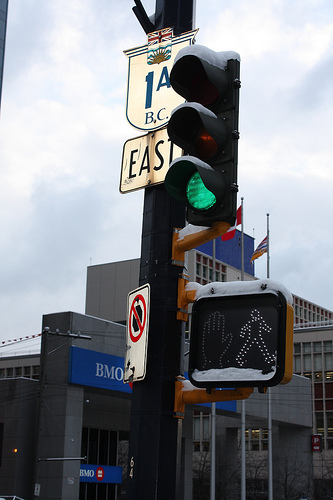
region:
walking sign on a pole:
[184, 269, 296, 409]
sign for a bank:
[77, 457, 126, 491]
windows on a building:
[309, 376, 331, 441]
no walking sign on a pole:
[121, 291, 156, 387]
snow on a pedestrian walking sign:
[200, 276, 282, 298]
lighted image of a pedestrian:
[232, 306, 279, 386]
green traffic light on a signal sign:
[159, 151, 229, 230]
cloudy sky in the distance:
[20, 10, 105, 210]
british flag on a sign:
[144, 25, 182, 50]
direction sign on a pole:
[113, 136, 183, 192]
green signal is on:
[157, 156, 227, 213]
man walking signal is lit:
[233, 308, 274, 365]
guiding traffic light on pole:
[182, 285, 293, 383]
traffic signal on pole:
[162, 38, 254, 246]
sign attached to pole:
[114, 281, 154, 394]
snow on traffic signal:
[183, 276, 295, 399]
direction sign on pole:
[114, 123, 187, 190]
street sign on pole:
[115, 22, 200, 133]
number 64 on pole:
[126, 454, 137, 487]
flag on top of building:
[247, 209, 276, 281]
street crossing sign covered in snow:
[186, 278, 295, 385]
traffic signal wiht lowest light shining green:
[161, 44, 240, 228]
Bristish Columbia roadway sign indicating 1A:
[122, 27, 200, 132]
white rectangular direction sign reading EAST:
[117, 126, 183, 194]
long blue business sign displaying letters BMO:
[67, 344, 238, 412]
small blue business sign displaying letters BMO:
[77, 464, 124, 483]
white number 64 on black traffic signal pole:
[125, 455, 135, 479]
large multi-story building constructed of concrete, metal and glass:
[0, 257, 332, 478]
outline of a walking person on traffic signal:
[235, 309, 277, 368]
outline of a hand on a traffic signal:
[200, 312, 232, 371]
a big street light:
[162, 42, 250, 233]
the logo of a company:
[79, 456, 119, 487]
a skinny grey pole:
[202, 417, 224, 483]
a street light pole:
[170, 379, 193, 405]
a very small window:
[309, 357, 328, 387]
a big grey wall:
[35, 395, 64, 442]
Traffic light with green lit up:
[160, 43, 242, 225]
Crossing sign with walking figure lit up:
[186, 293, 293, 387]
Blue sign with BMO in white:
[77, 463, 123, 484]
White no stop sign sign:
[122, 280, 148, 382]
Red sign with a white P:
[310, 432, 323, 452]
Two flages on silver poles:
[217, 193, 279, 282]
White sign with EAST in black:
[115, 123, 188, 193]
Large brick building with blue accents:
[3, 225, 332, 498]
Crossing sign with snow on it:
[174, 279, 297, 415]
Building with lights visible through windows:
[173, 323, 332, 499]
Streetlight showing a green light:
[161, 43, 242, 227]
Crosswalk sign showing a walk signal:
[173, 272, 295, 418]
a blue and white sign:
[65, 334, 145, 397]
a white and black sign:
[118, 279, 157, 387]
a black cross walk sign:
[172, 258, 301, 402]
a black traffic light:
[154, 31, 255, 245]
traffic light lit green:
[178, 171, 220, 216]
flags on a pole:
[204, 181, 282, 268]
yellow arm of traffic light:
[161, 207, 239, 270]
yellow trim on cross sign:
[274, 285, 303, 394]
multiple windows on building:
[294, 337, 332, 445]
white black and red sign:
[126, 292, 145, 379]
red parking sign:
[311, 433, 321, 449]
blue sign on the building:
[78, 462, 122, 482]